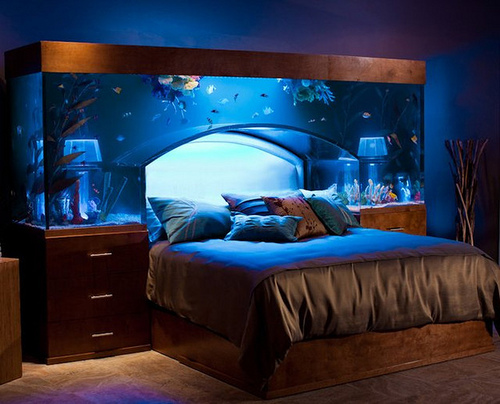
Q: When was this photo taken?
A: At night.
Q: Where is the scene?
A: Bedroom.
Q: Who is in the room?
A: No one.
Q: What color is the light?
A: Blue.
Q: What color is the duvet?
A: Dark brown.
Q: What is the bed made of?
A: Wood.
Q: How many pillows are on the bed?
A: 6.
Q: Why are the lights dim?
A: It's bedtime.